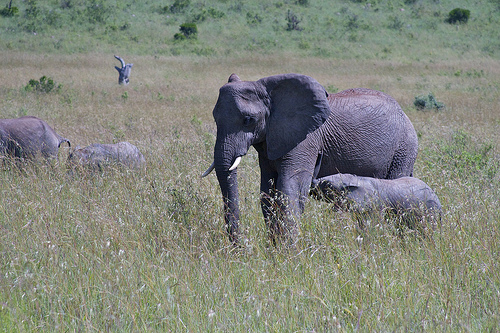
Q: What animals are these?
A: Elephants.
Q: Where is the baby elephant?
A: Next to the big one.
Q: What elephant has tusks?
A: The big one.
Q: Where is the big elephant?
A: On the left.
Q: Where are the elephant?
A: On a field.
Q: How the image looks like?
A: Cool.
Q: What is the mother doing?
A: Nursing baby elephant.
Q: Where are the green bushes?
A: On hill.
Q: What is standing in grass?
A: African elephant.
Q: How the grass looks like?
A: Dry.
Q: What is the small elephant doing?
A: Getting milk.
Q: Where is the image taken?
A: In a field.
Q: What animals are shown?
A: Elephants.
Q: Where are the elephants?
A: In the wild.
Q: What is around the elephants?
A: Grass.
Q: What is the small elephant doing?
A: Nursing.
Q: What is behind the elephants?
A: Grass.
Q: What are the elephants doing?
A: Standing.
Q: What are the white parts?
A: Tusks.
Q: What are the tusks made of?
A: Ivory.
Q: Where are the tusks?
A: On the elephants.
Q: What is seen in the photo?
A: Elephants.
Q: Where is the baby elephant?
A: Next to the adult elephant.